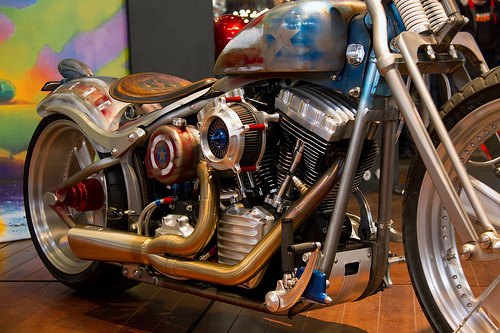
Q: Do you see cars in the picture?
A: No, there are no cars.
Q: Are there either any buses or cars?
A: No, there are no cars or buses.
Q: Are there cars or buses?
A: No, there are no cars or buses.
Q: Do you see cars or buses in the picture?
A: No, there are no cars or buses.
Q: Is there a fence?
A: No, there are no fences.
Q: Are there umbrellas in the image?
A: No, there are no umbrellas.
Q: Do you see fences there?
A: No, there are no fences.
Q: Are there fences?
A: No, there are no fences.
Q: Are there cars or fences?
A: No, there are no fences or cars.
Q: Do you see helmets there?
A: No, there are no helmets.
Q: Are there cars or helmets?
A: No, there are no helmets or cars.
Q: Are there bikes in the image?
A: Yes, there is a bike.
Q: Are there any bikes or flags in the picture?
A: Yes, there is a bike.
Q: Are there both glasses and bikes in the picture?
A: No, there is a bike but no glasses.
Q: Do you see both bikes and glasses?
A: No, there is a bike but no glasses.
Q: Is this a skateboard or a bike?
A: This is a bike.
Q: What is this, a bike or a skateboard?
A: This is a bike.